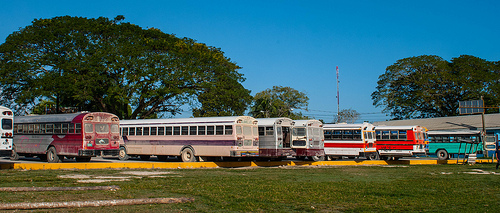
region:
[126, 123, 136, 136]
The window is square.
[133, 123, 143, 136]
The window is square.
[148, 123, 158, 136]
The window is square.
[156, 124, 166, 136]
The window is square.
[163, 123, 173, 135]
The window is square.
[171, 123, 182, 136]
The window is square.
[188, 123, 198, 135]
The window is square.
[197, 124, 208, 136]
The window is square.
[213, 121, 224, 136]
The window is square.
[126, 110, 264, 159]
this is a bus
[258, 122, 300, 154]
this is a bus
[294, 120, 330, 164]
this is a bus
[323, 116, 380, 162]
this is a bus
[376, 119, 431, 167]
this is a bus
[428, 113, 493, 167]
this is a bus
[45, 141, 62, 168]
this is a wheel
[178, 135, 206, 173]
this is a wheel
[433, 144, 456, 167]
this is a wheel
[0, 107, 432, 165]
the buses in the parking lot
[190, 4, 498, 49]
the sky is blue and clear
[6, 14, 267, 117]
the tall tree with green leaves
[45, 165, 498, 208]
the grass is short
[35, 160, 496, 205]
the grass is trimmed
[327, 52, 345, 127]
the tall pole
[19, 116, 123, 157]
the bus is red and silver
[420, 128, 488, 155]
the bus is green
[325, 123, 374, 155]
the bus is red and white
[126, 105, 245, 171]
purple stripe on the bus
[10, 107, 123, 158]
school bus parked in the parking lot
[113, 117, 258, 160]
school bus parked in the parking lot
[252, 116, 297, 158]
school bus parked in the parking lot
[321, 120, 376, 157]
school bus parked in the parking lot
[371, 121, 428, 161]
school bus parked in the parking lot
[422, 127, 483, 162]
school bus parked in the parking lot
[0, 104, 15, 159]
school bus parked in the parking lot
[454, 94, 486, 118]
Solar panel on roof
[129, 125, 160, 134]
Windows on a bus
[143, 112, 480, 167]
Buses parked in a row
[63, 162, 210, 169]
Curb painted with yellow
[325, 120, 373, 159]
White and red bus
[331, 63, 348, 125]
Tall pole made of metal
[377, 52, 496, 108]
Tree behind a building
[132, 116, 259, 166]
Purple and white bus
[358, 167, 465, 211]
Neatly trimmed grass lot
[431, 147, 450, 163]
Tire on a bus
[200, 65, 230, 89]
green leaves on the tree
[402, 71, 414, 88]
green leaves on the tree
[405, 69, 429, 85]
green leaves on the tree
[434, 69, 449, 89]
green leaves on the tree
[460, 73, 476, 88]
green leaves on the tree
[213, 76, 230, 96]
green leaves on the tree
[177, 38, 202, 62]
green leaves on the tree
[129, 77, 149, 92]
green leaves on the tree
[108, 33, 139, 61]
green leaves on the tree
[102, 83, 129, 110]
green leaves on the tree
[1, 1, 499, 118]
Bright blue stretch of sky.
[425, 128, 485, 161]
Turquoise colored bus with grey top.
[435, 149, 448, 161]
Round grey wheel on a turquiose bus.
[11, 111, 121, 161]
Grey and red bus parked.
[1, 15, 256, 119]
The largest green leafy tree.